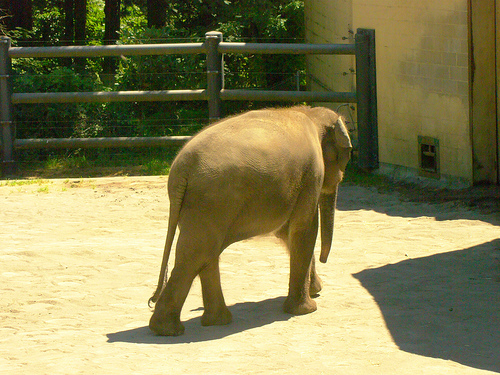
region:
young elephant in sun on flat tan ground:
[141, 98, 351, 334]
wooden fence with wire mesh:
[2, 35, 372, 175]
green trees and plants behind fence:
[2, 0, 308, 170]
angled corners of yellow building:
[302, 1, 492, 193]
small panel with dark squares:
[410, 130, 440, 175]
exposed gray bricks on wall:
[386, 5, 466, 110]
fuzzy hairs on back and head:
[165, 100, 340, 165]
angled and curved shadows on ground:
[335, 161, 491, 366]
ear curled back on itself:
[325, 111, 350, 151]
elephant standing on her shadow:
[136, 103, 352, 333]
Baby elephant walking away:
[146, 104, 353, 337]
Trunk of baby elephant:
[315, 186, 336, 263]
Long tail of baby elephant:
[145, 175, 190, 309]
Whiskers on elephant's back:
[170, 98, 340, 160]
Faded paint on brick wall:
[392, 3, 476, 112]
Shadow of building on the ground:
[348, 235, 498, 372]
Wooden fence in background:
[1, 30, 377, 170]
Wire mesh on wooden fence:
[0, 34, 362, 176]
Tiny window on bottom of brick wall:
[413, 133, 442, 174]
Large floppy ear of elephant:
[333, 115, 353, 172]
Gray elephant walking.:
[147, 98, 355, 335]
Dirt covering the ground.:
[2, 178, 497, 373]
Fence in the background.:
[0, 34, 385, 181]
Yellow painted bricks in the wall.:
[305, 0, 473, 181]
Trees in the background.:
[0, 0, 306, 175]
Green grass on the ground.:
[343, 168, 420, 200]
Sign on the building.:
[415, 133, 441, 180]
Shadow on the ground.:
[354, 215, 496, 374]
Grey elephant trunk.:
[311, 108, 351, 265]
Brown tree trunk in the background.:
[98, 2, 123, 74]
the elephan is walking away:
[151, 103, 356, 328]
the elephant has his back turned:
[151, 96, 347, 339]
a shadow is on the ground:
[109, 291, 308, 344]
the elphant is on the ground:
[108, 107, 351, 347]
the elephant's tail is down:
[141, 178, 186, 305]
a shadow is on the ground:
[359, 232, 499, 372]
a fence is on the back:
[2, 29, 380, 178]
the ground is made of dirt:
[3, 170, 498, 372]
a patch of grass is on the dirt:
[3, 179, 39, 185]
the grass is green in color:
[3, 181, 45, 186]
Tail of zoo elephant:
[151, 198, 170, 304]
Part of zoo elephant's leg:
[176, 243, 190, 291]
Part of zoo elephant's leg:
[200, 275, 220, 315]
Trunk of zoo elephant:
[318, 207, 333, 273]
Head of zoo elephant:
[318, 98, 356, 203]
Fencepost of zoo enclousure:
[348, 25, 380, 180]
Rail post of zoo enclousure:
[14, 43, 102, 58]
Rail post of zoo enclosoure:
[13, 85, 101, 104]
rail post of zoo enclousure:
[16, 133, 98, 153]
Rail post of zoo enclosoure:
[237, 37, 347, 61]